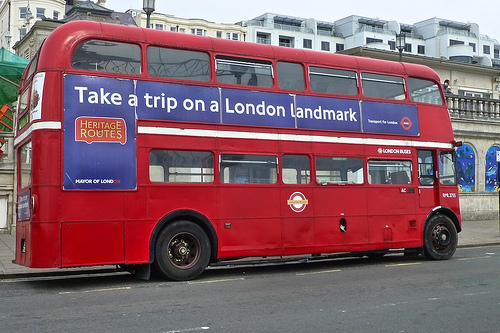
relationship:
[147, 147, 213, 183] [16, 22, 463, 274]
passenger window of bus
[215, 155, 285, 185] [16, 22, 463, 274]
window of bus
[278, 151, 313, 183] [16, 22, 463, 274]
window of bus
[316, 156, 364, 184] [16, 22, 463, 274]
passenger window of bus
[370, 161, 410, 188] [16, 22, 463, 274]
window of bus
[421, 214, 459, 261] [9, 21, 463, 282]
front tire of bus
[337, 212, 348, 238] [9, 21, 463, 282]
gas input for bus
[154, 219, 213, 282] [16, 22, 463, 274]
back wheel of bus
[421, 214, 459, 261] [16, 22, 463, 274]
front tire of bus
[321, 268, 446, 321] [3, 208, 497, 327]
gray pavement on street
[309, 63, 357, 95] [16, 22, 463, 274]
passenger window of bus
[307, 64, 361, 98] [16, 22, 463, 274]
window on bus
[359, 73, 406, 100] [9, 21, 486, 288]
window on bus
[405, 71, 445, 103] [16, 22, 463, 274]
window on bus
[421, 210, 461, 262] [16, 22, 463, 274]
front tire of bus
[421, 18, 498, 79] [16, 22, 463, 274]
building behind bus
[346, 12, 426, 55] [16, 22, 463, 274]
building behind bus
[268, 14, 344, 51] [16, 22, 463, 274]
building behind bus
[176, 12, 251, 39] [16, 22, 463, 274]
building behind bus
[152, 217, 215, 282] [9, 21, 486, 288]
back wheel on bus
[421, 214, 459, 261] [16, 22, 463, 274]
front tire on bus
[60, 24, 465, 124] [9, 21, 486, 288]
windows on bus